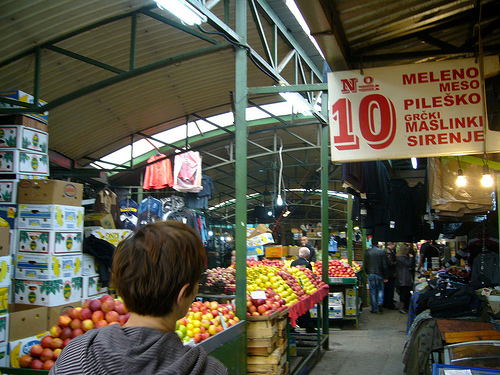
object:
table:
[269, 283, 330, 318]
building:
[0, 0, 500, 182]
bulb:
[455, 176, 467, 187]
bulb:
[481, 174, 493, 187]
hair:
[298, 247, 310, 257]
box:
[15, 225, 83, 256]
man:
[396, 243, 414, 314]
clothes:
[142, 153, 173, 189]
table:
[411, 269, 500, 375]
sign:
[325, 55, 485, 164]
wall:
[128, 126, 199, 161]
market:
[0, 0, 500, 375]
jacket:
[363, 246, 388, 279]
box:
[2, 124, 49, 153]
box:
[14, 251, 84, 280]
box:
[18, 178, 83, 206]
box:
[13, 275, 84, 306]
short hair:
[112, 219, 206, 316]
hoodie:
[46, 324, 230, 374]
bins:
[14, 203, 85, 232]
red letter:
[340, 78, 357, 94]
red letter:
[402, 73, 417, 85]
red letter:
[417, 72, 429, 83]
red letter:
[429, 71, 440, 82]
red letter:
[452, 68, 465, 80]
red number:
[332, 98, 359, 150]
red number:
[359, 93, 396, 149]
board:
[235, 0, 247, 372]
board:
[319, 90, 329, 316]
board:
[348, 191, 353, 268]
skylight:
[95, 89, 322, 175]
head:
[113, 220, 207, 320]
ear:
[177, 283, 192, 306]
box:
[246, 320, 276, 338]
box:
[239, 350, 288, 373]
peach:
[258, 306, 266, 313]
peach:
[266, 301, 273, 309]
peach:
[252, 311, 260, 317]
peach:
[247, 301, 252, 306]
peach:
[274, 295, 281, 301]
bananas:
[47, 255, 82, 281]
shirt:
[172, 150, 203, 193]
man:
[364, 237, 390, 313]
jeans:
[368, 273, 384, 310]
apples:
[0, 291, 238, 374]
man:
[299, 236, 317, 263]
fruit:
[244, 261, 329, 317]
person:
[45, 222, 225, 374]